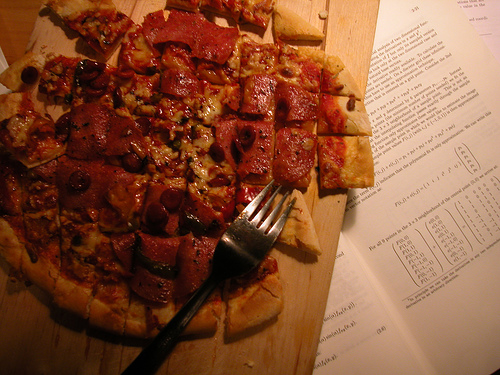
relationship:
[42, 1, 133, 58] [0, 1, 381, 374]
piece of board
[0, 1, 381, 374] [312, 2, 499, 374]
board occludes paper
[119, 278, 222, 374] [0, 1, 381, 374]
handle rests on board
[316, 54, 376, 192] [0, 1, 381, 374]
edge of board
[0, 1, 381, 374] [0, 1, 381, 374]
board on board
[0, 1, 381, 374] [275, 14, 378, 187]
board has crust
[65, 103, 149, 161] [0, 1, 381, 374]
pepperoni on board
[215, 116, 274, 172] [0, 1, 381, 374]
pepperoni on board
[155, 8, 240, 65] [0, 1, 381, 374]
pepperoni on board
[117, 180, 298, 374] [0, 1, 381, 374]
fork on board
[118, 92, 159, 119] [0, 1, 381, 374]
susage on top of board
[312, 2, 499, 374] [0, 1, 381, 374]
paper under board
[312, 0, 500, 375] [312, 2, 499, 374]
paper on paper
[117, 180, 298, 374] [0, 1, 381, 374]
fork on top of board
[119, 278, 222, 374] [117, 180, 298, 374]
handle apart of fork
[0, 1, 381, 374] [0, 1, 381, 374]
board on top of board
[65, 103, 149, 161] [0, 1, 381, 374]
pepperoni on top of board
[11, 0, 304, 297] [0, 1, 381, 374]
cheese on top of board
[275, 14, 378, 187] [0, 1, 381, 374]
crust apart of board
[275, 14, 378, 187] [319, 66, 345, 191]
crust has tomatoe sauce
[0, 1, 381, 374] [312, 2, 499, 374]
board on top of paper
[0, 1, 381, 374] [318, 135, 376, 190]
board cut in to squares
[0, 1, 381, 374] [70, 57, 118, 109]
board cut in to squares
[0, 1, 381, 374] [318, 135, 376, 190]
board cut into squares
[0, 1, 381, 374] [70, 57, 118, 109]
board cut into squares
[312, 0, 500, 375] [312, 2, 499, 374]
paper on top of paper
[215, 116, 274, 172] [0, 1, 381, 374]
pepperoni on top of board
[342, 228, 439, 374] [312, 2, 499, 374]
crease of paper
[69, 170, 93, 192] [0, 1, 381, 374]
olives on top of board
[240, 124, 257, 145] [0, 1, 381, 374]
olives on top of board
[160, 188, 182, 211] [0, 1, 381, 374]
olives on top of board